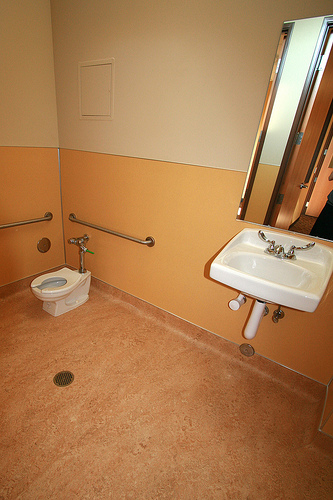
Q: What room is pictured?
A: It is a bathroom.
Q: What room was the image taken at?
A: It was taken at the bathroom.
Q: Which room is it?
A: It is a bathroom.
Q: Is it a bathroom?
A: Yes, it is a bathroom.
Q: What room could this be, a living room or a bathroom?
A: It is a bathroom.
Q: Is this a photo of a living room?
A: No, the picture is showing a bathroom.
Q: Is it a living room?
A: No, it is a bathroom.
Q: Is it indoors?
A: Yes, it is indoors.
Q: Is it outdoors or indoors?
A: It is indoors.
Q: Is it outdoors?
A: No, it is indoors.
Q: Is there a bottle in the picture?
A: No, there are no bottles.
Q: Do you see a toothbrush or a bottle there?
A: No, there are no bottles or toothbrushes.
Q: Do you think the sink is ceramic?
A: Yes, the sink is ceramic.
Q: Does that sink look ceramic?
A: Yes, the sink is ceramic.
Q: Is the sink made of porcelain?
A: Yes, the sink is made of porcelain.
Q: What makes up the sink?
A: The sink is made of porcelain.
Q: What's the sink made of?
A: The sink is made of porcelain.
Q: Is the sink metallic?
A: No, the sink is ceramic.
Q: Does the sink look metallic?
A: No, the sink is ceramic.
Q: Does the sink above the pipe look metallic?
A: No, the sink is ceramic.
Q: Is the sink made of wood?
A: No, the sink is made of porcelain.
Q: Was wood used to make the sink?
A: No, the sink is made of porcelain.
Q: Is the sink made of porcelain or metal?
A: The sink is made of porcelain.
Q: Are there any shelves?
A: No, there are no shelves.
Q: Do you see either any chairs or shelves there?
A: No, there are no shelves or chairs.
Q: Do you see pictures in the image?
A: No, there are no pictures.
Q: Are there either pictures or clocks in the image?
A: No, there are no pictures or clocks.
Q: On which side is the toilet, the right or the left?
A: The toilet is on the left of the image.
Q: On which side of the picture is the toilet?
A: The toilet is on the left of the image.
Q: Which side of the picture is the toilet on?
A: The toilet is on the left of the image.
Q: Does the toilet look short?
A: Yes, the toilet is short.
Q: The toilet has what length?
A: The toilet is short.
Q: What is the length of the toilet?
A: The toilet is short.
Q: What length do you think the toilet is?
A: The toilet is short.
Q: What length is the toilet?
A: The toilet is short.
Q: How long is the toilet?
A: The toilet is short.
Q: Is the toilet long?
A: No, the toilet is short.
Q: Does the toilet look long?
A: No, the toilet is short.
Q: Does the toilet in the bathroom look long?
A: No, the toilet is short.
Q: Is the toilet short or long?
A: The toilet is short.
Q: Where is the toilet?
A: The toilet is in the bathroom.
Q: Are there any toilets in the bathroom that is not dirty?
A: Yes, there is a toilet in the bathroom.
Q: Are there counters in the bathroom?
A: No, there is a toilet in the bathroom.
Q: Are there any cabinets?
A: No, there are no cabinets.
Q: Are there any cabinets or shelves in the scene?
A: No, there are no cabinets or shelves.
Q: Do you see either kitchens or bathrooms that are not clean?
A: No, there is a bathroom but it is clean.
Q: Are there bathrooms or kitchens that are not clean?
A: No, there is a bathroom but it is clean.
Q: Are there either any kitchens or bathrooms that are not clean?
A: No, there is a bathroom but it is clean.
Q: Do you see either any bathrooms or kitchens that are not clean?
A: No, there is a bathroom but it is clean.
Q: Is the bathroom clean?
A: Yes, the bathroom is clean.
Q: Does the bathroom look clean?
A: Yes, the bathroom is clean.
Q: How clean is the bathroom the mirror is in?
A: The bathroom is clean.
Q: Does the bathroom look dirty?
A: No, the bathroom is clean.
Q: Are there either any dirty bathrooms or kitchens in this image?
A: No, there is a bathroom but it is clean.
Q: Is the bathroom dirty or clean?
A: The bathroom is clean.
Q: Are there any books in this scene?
A: No, there are no books.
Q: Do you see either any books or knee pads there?
A: No, there are no books or knee pads.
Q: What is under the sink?
A: The pipe is under the sink.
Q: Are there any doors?
A: Yes, there is a door.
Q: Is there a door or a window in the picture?
A: Yes, there is a door.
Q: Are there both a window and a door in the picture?
A: No, there is a door but no windows.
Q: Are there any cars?
A: No, there are no cars.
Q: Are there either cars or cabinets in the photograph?
A: No, there are no cars or cabinets.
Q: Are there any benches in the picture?
A: No, there are no benches.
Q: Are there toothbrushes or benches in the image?
A: No, there are no benches or toothbrushes.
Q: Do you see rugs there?
A: No, there are no rugs.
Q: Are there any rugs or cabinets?
A: No, there are no rugs or cabinets.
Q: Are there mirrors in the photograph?
A: Yes, there is a mirror.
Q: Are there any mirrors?
A: Yes, there is a mirror.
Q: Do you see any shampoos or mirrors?
A: Yes, there is a mirror.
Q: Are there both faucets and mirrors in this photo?
A: Yes, there are both a mirror and a faucet.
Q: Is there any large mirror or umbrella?
A: Yes, there is a large mirror.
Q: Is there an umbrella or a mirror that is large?
A: Yes, the mirror is large.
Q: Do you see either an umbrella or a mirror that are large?
A: Yes, the mirror is large.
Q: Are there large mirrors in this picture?
A: Yes, there is a large mirror.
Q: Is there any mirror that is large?
A: Yes, there is a mirror that is large.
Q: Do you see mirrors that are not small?
A: Yes, there is a large mirror.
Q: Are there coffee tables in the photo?
A: No, there are no coffee tables.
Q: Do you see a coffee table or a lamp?
A: No, there are no coffee tables or lamps.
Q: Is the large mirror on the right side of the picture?
A: Yes, the mirror is on the right of the image.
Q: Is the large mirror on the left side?
A: No, the mirror is on the right of the image.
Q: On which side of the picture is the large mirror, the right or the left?
A: The mirror is on the right of the image.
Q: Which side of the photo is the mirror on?
A: The mirror is on the right of the image.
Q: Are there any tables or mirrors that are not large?
A: No, there is a mirror but it is large.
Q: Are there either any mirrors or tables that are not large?
A: No, there is a mirror but it is large.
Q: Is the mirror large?
A: Yes, the mirror is large.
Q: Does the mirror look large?
A: Yes, the mirror is large.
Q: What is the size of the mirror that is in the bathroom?
A: The mirror is large.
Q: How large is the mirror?
A: The mirror is large.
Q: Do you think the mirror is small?
A: No, the mirror is large.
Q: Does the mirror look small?
A: No, the mirror is large.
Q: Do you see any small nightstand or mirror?
A: No, there is a mirror but it is large.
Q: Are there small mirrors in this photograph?
A: No, there is a mirror but it is large.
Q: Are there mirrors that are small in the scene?
A: No, there is a mirror but it is large.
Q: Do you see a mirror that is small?
A: No, there is a mirror but it is large.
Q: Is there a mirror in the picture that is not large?
A: No, there is a mirror but it is large.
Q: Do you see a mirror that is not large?
A: No, there is a mirror but it is large.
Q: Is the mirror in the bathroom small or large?
A: The mirror is large.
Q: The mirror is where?
A: The mirror is in the bathroom.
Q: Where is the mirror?
A: The mirror is in the bathroom.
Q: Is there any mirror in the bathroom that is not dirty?
A: Yes, there is a mirror in the bathroom.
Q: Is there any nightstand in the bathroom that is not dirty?
A: No, there is a mirror in the bathroom.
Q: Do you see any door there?
A: Yes, there is a door.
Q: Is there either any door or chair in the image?
A: Yes, there is a door.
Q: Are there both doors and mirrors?
A: Yes, there are both a door and a mirror.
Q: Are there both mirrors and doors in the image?
A: Yes, there are both a door and a mirror.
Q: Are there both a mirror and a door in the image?
A: Yes, there are both a door and a mirror.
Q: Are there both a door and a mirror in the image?
A: Yes, there are both a door and a mirror.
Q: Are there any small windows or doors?
A: Yes, there is a small door.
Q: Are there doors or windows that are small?
A: Yes, the door is small.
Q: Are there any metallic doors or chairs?
A: Yes, there is a metal door.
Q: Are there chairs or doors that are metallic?
A: Yes, the door is metallic.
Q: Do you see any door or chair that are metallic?
A: Yes, the door is metallic.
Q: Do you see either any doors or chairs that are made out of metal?
A: Yes, the door is made of metal.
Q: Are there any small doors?
A: Yes, there is a small door.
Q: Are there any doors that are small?
A: Yes, there is a door that is small.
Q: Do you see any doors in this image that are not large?
A: Yes, there is a small door.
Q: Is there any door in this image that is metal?
A: Yes, there is a metal door.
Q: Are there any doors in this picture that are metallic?
A: Yes, there is a door that is metallic.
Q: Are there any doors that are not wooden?
A: Yes, there is a metallic door.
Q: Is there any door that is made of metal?
A: Yes, there is a door that is made of metal.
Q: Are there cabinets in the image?
A: No, there are no cabinets.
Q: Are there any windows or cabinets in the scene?
A: No, there are no cabinets or windows.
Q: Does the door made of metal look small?
A: Yes, the door is small.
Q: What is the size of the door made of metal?
A: The door is small.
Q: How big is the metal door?
A: The door is small.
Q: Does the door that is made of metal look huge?
A: No, the door is small.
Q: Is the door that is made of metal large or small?
A: The door is small.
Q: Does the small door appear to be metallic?
A: Yes, the door is metallic.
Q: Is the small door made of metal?
A: Yes, the door is made of metal.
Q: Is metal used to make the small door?
A: Yes, the door is made of metal.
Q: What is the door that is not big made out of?
A: The door is made of metal.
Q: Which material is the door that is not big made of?
A: The door is made of metal.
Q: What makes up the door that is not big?
A: The door is made of metal.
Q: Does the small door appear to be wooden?
A: No, the door is metallic.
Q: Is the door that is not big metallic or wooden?
A: The door is metallic.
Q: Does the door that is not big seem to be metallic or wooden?
A: The door is metallic.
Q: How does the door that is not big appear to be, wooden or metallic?
A: The door is metallic.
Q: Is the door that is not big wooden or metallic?
A: The door is metallic.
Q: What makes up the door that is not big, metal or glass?
A: The door is made of metal.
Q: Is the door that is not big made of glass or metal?
A: The door is made of metal.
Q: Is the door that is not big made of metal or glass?
A: The door is made of metal.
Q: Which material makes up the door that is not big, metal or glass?
A: The door is made of metal.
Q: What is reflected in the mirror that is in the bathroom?
A: The door is reflected in the mirror.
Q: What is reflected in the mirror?
A: The door is reflected in the mirror.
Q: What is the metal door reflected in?
A: The door is reflected in the mirror.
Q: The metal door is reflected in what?
A: The door is reflected in the mirror.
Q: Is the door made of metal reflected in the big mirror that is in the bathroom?
A: Yes, the door is reflected in the mirror.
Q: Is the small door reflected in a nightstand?
A: No, the door is reflected in the mirror.